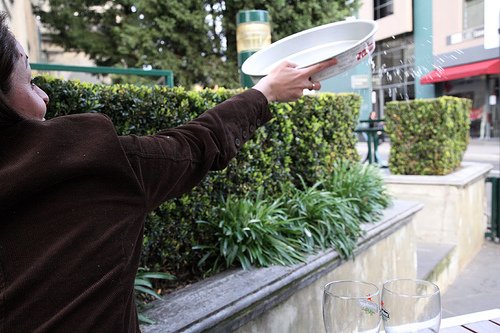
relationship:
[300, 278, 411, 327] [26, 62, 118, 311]
glasses near person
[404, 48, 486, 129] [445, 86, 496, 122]
store has front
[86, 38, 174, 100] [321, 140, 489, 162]
handrail near sidewalk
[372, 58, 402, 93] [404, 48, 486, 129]
window on store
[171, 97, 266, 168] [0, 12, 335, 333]
sleeves on person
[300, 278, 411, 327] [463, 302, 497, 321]
glasses on table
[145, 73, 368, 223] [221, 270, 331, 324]
plants above wall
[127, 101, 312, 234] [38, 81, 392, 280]
bushes are near plants